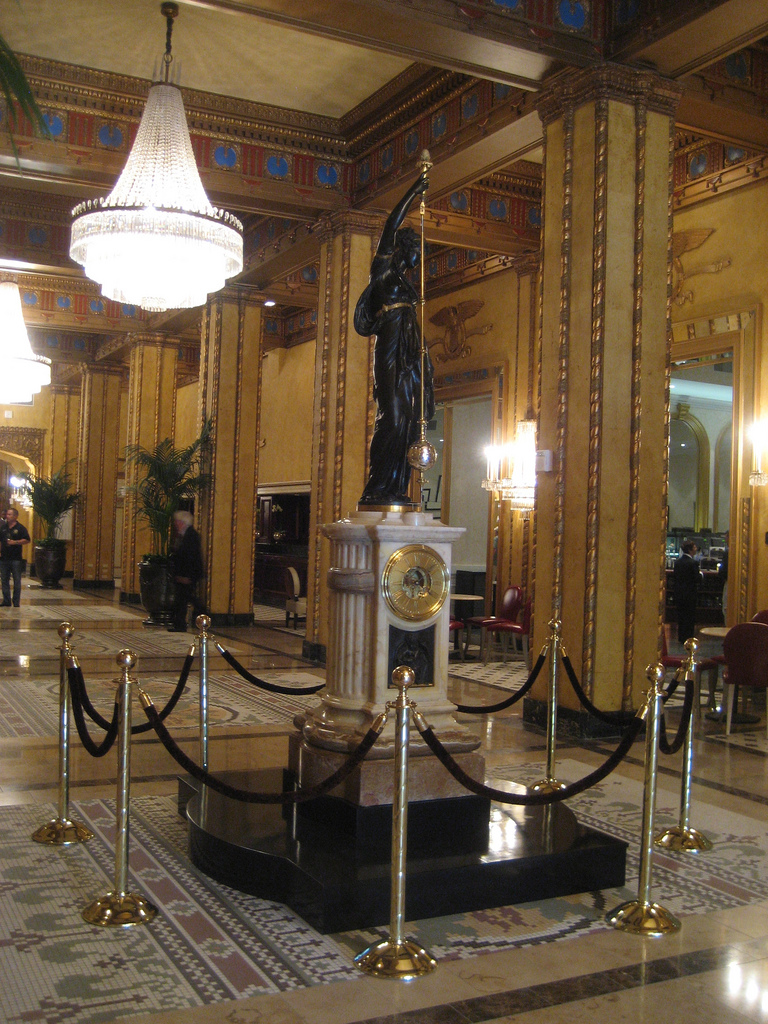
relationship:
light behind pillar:
[483, 419, 548, 506] [522, 95, 681, 734]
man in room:
[160, 504, 228, 637] [0, 2, 742, 1015]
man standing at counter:
[674, 539, 704, 643] [698, 538, 729, 618]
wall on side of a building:
[256, 340, 316, 484] [0, 0, 768, 1022]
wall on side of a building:
[254, 344, 415, 458] [0, 0, 768, 1022]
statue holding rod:
[353, 139, 442, 513] [406, 139, 443, 480]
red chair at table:
[473, 578, 522, 666] [445, 588, 484, 666]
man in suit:
[168, 509, 203, 631] [169, 533, 219, 590]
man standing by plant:
[168, 509, 203, 631] [128, 426, 206, 557]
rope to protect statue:
[54, 640, 704, 806] [350, 143, 450, 513]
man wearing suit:
[669, 531, 704, 651] [659, 544, 726, 651]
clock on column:
[379, 546, 443, 622] [306, 506, 468, 743]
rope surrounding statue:
[56, 643, 131, 758] [350, 175, 447, 508]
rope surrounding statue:
[216, 629, 332, 697] [350, 175, 447, 508]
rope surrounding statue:
[445, 635, 552, 715] [350, 175, 447, 508]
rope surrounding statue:
[556, 638, 686, 712] [350, 175, 447, 508]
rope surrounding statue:
[412, 704, 659, 804] [350, 175, 447, 508]